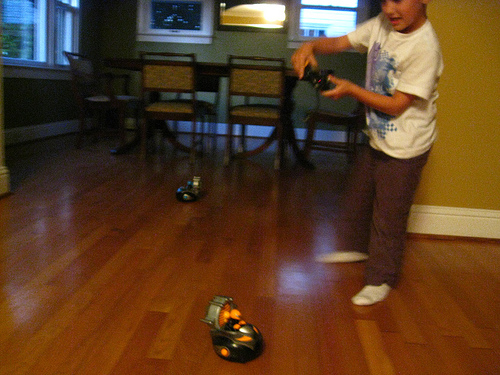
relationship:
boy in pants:
[277, 0, 453, 306] [352, 129, 436, 292]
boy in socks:
[277, 0, 453, 306] [316, 250, 391, 305]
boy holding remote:
[277, 0, 453, 306] [292, 59, 372, 115]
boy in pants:
[277, 0, 453, 306] [330, 131, 444, 293]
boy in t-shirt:
[277, 0, 453, 306] [343, 7, 442, 158]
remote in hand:
[298, 68, 332, 90] [326, 77, 343, 99]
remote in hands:
[298, 68, 332, 90] [290, 49, 351, 101]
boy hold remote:
[277, 0, 453, 306] [298, 68, 332, 90]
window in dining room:
[1, 0, 79, 67] [0, 0, 382, 222]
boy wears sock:
[277, 0, 453, 306] [348, 279, 388, 306]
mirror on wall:
[215, 0, 291, 29] [100, 4, 359, 176]